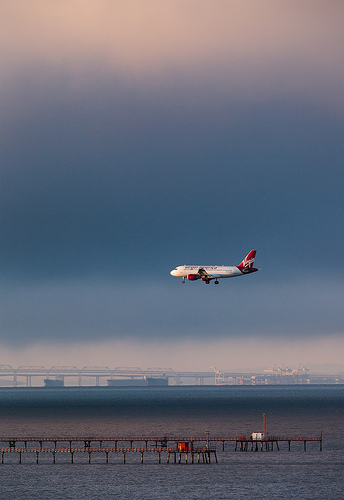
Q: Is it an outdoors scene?
A: Yes, it is outdoors.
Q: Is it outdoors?
A: Yes, it is outdoors.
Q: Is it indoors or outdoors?
A: It is outdoors.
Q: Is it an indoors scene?
A: No, it is outdoors.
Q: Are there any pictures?
A: No, there are no pictures.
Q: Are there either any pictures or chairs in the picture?
A: No, there are no pictures or chairs.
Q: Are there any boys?
A: No, there are no boys.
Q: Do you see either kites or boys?
A: No, there are no boys or kites.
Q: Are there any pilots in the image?
A: No, there are no pilots.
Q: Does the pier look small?
A: Yes, the pier is small.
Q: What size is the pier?
A: The pier is small.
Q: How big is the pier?
A: The pier is small.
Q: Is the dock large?
A: No, the dock is small.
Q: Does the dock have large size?
A: No, the dock is small.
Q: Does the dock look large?
A: No, the dock is small.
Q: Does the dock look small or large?
A: The dock is small.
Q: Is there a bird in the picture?
A: No, there are no birds.